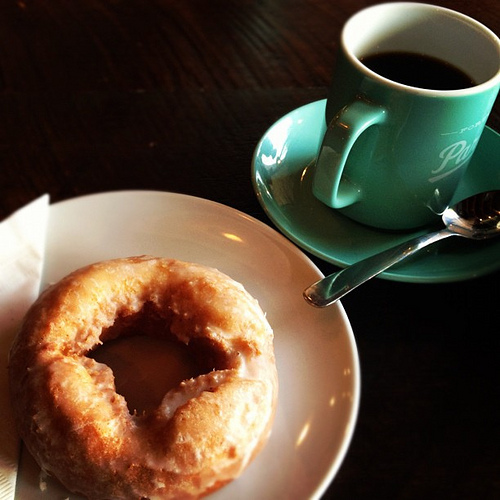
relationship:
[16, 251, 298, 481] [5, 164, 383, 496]
donut on plate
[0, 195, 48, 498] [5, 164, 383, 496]
napkin on plate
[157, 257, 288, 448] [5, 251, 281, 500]
glaze on donut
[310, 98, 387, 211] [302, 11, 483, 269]
handle on cup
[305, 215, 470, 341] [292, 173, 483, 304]
handle on spoon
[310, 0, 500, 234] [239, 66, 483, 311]
coffee cup on plate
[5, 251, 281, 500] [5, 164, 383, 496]
donut on plate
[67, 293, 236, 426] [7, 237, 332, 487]
hole in donut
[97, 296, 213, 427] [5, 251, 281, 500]
hole in donut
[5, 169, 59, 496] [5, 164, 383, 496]
napkin on plate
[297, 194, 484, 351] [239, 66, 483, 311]
spoon on plate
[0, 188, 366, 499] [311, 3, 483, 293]
plate underneath cup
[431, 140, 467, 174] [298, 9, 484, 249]
writing on cup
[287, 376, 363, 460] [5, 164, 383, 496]
reflection on plate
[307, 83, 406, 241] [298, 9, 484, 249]
handle on cup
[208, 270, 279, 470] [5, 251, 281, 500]
glaze on donut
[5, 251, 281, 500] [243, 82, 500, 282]
donut on plate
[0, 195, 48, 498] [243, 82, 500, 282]
napkin on plate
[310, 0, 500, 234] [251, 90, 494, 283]
coffee cup on saucer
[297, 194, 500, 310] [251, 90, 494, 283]
spoon on saucer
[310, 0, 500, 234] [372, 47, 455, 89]
coffee cup filled with coffee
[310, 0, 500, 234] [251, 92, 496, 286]
coffee cup on plate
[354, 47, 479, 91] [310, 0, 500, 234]
coffee in coffee cup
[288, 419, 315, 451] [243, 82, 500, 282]
light reflected on plate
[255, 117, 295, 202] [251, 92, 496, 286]
reflection on plate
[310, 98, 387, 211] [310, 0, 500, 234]
handle on coffee cup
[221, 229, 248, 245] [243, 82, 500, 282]
light on plate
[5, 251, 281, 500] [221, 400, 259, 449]
donut with glaze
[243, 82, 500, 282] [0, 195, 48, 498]
plate holding napkin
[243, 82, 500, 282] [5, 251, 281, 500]
plate holding donut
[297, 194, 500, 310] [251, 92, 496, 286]
spoon resting on plate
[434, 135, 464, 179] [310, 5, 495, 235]
writing on coffee cup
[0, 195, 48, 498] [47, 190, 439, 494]
napkin on plate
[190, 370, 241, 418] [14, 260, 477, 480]
bubble on donut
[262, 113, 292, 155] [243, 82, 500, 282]
light on plate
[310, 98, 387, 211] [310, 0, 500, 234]
handle of coffee cup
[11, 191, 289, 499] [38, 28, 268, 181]
plate on table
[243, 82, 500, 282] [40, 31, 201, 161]
plate on table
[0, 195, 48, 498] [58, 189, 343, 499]
napkin on plate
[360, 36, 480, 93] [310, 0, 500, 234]
coffee in coffee cup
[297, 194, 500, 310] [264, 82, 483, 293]
spoon on plate